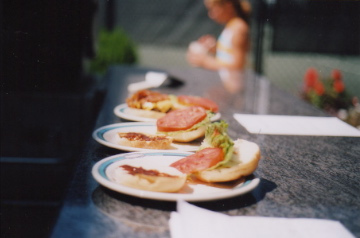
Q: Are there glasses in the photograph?
A: No, there are no glasses.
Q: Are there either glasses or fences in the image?
A: No, there are no glasses or fences.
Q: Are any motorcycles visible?
A: No, there are no motorcycles.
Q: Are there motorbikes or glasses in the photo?
A: No, there are no motorbikes or glasses.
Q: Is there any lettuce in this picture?
A: Yes, there is lettuce.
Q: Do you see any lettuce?
A: Yes, there is lettuce.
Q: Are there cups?
A: No, there are no cups.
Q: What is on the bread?
A: The lettuce is on the bread.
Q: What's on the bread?
A: The lettuce is on the bread.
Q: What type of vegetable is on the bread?
A: The vegetable is lettuce.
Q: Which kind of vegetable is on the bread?
A: The vegetable is lettuce.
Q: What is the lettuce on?
A: The lettuce is on the bread.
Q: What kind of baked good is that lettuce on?
A: The lettuce is on the bread.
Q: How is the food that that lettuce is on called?
A: The food is a bread.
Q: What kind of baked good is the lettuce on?
A: The lettuce is on the bread.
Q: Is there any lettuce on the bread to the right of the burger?
A: Yes, there is lettuce on the bread.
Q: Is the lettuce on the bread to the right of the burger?
A: Yes, the lettuce is on the bread.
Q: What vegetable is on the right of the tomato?
A: The vegetable is lettuce.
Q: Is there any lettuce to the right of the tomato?
A: Yes, there is lettuce to the right of the tomato.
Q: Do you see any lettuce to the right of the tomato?
A: Yes, there is lettuce to the right of the tomato.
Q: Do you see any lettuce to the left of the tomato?
A: No, the lettuce is to the right of the tomato.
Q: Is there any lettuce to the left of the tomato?
A: No, the lettuce is to the right of the tomato.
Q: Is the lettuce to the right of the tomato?
A: Yes, the lettuce is to the right of the tomato.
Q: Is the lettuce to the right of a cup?
A: No, the lettuce is to the right of the tomato.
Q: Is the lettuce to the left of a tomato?
A: No, the lettuce is to the right of a tomato.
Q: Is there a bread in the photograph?
A: Yes, there is a bread.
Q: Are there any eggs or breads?
A: Yes, there is a bread.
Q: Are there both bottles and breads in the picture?
A: No, there is a bread but no bottles.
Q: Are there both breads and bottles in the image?
A: No, there is a bread but no bottles.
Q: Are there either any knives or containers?
A: No, there are no containers or knives.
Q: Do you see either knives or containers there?
A: No, there are no containers or knives.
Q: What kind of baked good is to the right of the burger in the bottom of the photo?
A: The food is a bread.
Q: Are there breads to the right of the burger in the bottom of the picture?
A: Yes, there is a bread to the right of the burger.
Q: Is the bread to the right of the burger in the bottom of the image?
A: Yes, the bread is to the right of the burger.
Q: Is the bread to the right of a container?
A: No, the bread is to the right of the burger.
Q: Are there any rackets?
A: No, there are no rackets.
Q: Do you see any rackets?
A: No, there are no rackets.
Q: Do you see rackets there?
A: No, there are no rackets.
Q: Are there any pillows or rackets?
A: No, there are no rackets or pillows.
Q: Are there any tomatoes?
A: Yes, there is a tomato.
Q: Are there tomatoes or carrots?
A: Yes, there is a tomato.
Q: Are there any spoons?
A: No, there are no spoons.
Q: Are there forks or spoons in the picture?
A: No, there are no spoons or forks.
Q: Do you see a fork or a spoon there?
A: No, there are no spoons or forks.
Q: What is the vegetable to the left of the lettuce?
A: The vegetable is a tomato.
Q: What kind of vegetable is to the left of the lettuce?
A: The vegetable is a tomato.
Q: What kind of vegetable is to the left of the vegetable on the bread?
A: The vegetable is a tomato.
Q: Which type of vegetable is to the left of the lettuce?
A: The vegetable is a tomato.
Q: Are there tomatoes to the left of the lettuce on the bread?
A: Yes, there is a tomato to the left of the lettuce.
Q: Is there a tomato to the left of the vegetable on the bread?
A: Yes, there is a tomato to the left of the lettuce.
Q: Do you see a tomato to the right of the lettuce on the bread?
A: No, the tomato is to the left of the lettuce.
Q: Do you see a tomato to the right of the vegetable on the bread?
A: No, the tomato is to the left of the lettuce.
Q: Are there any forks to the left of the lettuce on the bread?
A: No, there is a tomato to the left of the lettuce.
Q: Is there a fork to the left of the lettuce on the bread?
A: No, there is a tomato to the left of the lettuce.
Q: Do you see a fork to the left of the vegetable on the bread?
A: No, there is a tomato to the left of the lettuce.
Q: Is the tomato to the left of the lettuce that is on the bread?
A: Yes, the tomato is to the left of the lettuce.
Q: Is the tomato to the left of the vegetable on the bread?
A: Yes, the tomato is to the left of the lettuce.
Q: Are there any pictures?
A: No, there are no pictures.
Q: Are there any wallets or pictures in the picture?
A: No, there are no pictures or wallets.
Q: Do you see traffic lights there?
A: No, there are no traffic lights.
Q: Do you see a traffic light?
A: No, there are no traffic lights.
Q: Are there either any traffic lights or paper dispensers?
A: No, there are no traffic lights or paper dispensers.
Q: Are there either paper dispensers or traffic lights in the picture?
A: No, there are no traffic lights or paper dispensers.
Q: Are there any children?
A: Yes, there is a child.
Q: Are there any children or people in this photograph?
A: Yes, there is a child.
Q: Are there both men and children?
A: No, there is a child but no men.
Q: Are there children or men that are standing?
A: Yes, the child is standing.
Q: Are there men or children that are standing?
A: Yes, the child is standing.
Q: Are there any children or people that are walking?
A: Yes, the child is walking.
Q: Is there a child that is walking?
A: Yes, there is a child that is walking.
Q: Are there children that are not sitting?
A: Yes, there is a child that is walking.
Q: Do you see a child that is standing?
A: Yes, there is a child that is standing.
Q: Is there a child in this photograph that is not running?
A: Yes, there is a child that is standing.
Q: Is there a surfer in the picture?
A: No, there are no surfers.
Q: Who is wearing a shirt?
A: The child is wearing a shirt.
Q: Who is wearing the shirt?
A: The child is wearing a shirt.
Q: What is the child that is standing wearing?
A: The child is wearing a shirt.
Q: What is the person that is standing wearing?
A: The child is wearing a shirt.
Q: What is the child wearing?
A: The child is wearing a shirt.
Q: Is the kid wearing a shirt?
A: Yes, the kid is wearing a shirt.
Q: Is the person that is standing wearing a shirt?
A: Yes, the kid is wearing a shirt.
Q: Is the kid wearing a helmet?
A: No, the kid is wearing a shirt.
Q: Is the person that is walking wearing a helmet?
A: No, the kid is wearing a shirt.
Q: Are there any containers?
A: No, there are no containers.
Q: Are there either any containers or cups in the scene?
A: No, there are no containers or cups.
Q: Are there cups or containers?
A: No, there are no containers or cups.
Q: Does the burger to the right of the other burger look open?
A: Yes, the burger is open.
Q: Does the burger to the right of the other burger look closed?
A: No, the burger is open.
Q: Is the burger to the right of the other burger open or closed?
A: The burger is open.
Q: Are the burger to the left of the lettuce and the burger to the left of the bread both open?
A: Yes, both the burger and the burger are open.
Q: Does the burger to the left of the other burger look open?
A: Yes, the burger is open.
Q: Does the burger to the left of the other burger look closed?
A: No, the burger is open.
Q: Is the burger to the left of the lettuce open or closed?
A: The burger is open.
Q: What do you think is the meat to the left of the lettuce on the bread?
A: The meat is a burger.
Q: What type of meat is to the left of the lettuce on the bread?
A: The meat is a burger.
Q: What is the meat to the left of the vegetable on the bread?
A: The meat is a burger.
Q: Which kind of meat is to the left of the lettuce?
A: The meat is a burger.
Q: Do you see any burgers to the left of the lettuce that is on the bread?
A: Yes, there is a burger to the left of the lettuce.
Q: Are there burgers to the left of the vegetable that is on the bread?
A: Yes, there is a burger to the left of the lettuce.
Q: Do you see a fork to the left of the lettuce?
A: No, there is a burger to the left of the lettuce.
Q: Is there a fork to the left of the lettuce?
A: No, there is a burger to the left of the lettuce.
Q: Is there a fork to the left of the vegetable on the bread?
A: No, there is a burger to the left of the lettuce.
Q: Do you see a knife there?
A: No, there are no knives.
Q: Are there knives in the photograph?
A: No, there are no knives.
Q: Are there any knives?
A: No, there are no knives.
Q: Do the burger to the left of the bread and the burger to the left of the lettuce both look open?
A: Yes, both the burger and the burger are open.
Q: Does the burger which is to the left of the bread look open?
A: Yes, the burger is open.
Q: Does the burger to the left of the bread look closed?
A: No, the burger is open.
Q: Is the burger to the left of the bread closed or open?
A: The burger is open.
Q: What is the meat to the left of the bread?
A: The meat is a burger.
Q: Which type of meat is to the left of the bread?
A: The meat is a burger.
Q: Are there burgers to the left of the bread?
A: Yes, there is a burger to the left of the bread.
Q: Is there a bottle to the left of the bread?
A: No, there is a burger to the left of the bread.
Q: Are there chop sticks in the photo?
A: No, there are no chop sticks.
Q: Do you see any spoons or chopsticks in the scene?
A: No, there are no chopsticks or spoons.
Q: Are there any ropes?
A: No, there are no ropes.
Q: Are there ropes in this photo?
A: No, there are no ropes.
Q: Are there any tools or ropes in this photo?
A: No, there are no ropes or tools.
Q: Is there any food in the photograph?
A: Yes, there is food.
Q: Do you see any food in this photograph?
A: Yes, there is food.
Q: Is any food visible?
A: Yes, there is food.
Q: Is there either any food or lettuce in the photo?
A: Yes, there is food.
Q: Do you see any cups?
A: No, there are no cups.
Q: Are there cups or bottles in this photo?
A: No, there are no cups or bottles.